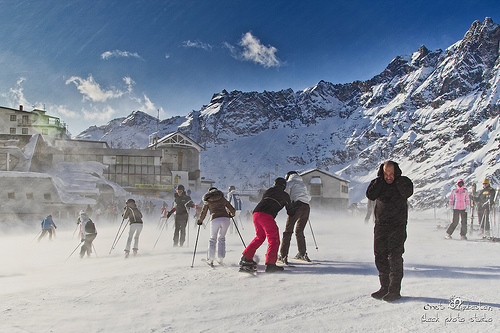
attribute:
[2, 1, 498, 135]
sky — blue, clear, cloudy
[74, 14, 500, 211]
mountains — snowy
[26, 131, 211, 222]
building — glass, windowed, far, large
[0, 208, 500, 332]
snow — blowing, blown, white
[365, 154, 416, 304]
man — not listening, standing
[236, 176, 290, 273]
man — skating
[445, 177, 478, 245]
person — standing, frozen, skiing, not alone, here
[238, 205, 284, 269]
pants — red, here, pink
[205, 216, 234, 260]
pants — white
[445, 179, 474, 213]
jacket — pink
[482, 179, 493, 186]
hat — yellow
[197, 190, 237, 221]
jacket — brown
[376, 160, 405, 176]
gloves — black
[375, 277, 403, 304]
boots — black